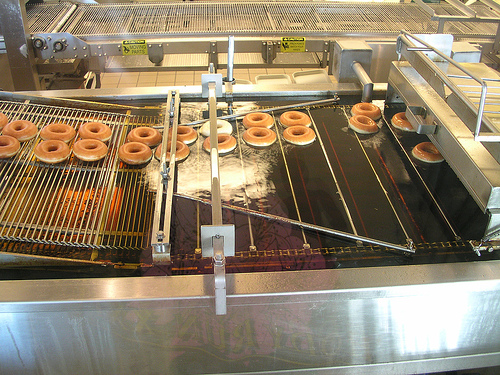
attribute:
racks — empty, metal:
[0, 0, 496, 38]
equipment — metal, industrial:
[6, 44, 490, 373]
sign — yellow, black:
[275, 31, 312, 62]